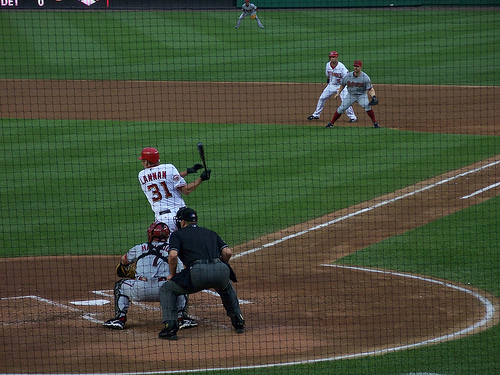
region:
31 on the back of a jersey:
[141, 173, 178, 208]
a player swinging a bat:
[182, 137, 221, 186]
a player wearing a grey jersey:
[122, 233, 187, 286]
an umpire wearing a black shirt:
[158, 222, 237, 273]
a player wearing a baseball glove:
[362, 86, 382, 111]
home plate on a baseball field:
[54, 281, 113, 320]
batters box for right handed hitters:
[0, 270, 100, 338]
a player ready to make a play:
[318, 54, 387, 140]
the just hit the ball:
[110, 95, 251, 291]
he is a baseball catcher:
[103, 214, 219, 344]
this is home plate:
[46, 278, 111, 310]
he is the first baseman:
[319, 57, 387, 139]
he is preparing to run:
[287, 35, 398, 140]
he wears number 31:
[139, 172, 181, 213]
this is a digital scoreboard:
[1, 1, 111, 8]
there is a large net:
[2, 2, 499, 372]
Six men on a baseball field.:
[21, 3, 473, 359]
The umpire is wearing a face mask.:
[156, 205, 248, 343]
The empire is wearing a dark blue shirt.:
[161, 197, 241, 274]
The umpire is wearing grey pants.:
[158, 200, 248, 346]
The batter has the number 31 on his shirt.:
[126, 125, 220, 215]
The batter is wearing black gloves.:
[130, 122, 227, 199]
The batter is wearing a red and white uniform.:
[130, 134, 210, 227]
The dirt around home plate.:
[3, 228, 492, 374]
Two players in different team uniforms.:
[307, 45, 384, 130]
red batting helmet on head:
[140, 144, 162, 165]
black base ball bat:
[193, 137, 213, 173]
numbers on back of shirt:
[138, 165, 170, 207]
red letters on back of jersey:
[138, 169, 170, 186]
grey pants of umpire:
[160, 254, 240, 319]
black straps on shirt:
[138, 241, 171, 269]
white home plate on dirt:
[71, 290, 110, 315]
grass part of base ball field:
[361, 206, 487, 283]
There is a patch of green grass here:
[266, 147, 282, 194]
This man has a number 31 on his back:
[149, 183, 167, 200]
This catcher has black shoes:
[111, 316, 128, 337]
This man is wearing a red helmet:
[143, 145, 159, 179]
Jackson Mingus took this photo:
[95, 77, 244, 338]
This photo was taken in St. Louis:
[98, 53, 275, 344]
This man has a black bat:
[196, 144, 219, 192]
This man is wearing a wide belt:
[158, 208, 164, 215]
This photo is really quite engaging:
[125, 57, 265, 370]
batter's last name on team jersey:
[137, 170, 168, 186]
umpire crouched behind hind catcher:
[153, 204, 248, 343]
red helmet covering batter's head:
[136, 146, 164, 168]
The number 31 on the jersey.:
[150, 180, 173, 210]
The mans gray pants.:
[153, 264, 248, 328]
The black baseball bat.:
[196, 138, 213, 180]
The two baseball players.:
[312, 51, 387, 131]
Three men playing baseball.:
[98, 122, 237, 343]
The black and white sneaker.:
[104, 314, 126, 336]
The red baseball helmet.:
[141, 142, 162, 170]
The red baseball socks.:
[332, 106, 382, 128]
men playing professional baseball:
[2, 1, 499, 350]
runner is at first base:
[305, 52, 357, 130]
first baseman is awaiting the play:
[327, 57, 386, 128]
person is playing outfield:
[233, 3, 269, 26]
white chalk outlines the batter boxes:
[0, 282, 248, 327]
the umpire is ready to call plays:
[156, 205, 248, 338]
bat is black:
[198, 141, 209, 173]